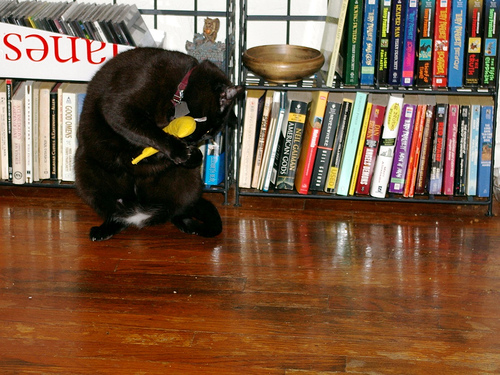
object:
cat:
[72, 44, 244, 243]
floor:
[0, 180, 499, 374]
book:
[335, 0, 360, 87]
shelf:
[238, 0, 495, 213]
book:
[360, 1, 377, 86]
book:
[376, 0, 391, 87]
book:
[389, 2, 403, 88]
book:
[400, 0, 418, 87]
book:
[416, 0, 433, 88]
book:
[433, 1, 450, 88]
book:
[448, 1, 465, 88]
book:
[462, 1, 484, 88]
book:
[480, 0, 496, 88]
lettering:
[3, 31, 121, 64]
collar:
[169, 62, 197, 111]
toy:
[129, 115, 198, 165]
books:
[455, 104, 472, 198]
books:
[2, 85, 12, 185]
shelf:
[1, 0, 237, 193]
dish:
[241, 42, 325, 85]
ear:
[222, 80, 247, 103]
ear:
[228, 106, 242, 128]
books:
[321, 1, 498, 89]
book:
[296, 89, 330, 193]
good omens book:
[60, 82, 85, 182]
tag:
[173, 96, 190, 119]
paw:
[168, 137, 190, 166]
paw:
[183, 145, 203, 169]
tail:
[186, 195, 224, 236]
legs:
[80, 207, 135, 244]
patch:
[110, 201, 155, 230]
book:
[477, 97, 494, 200]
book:
[204, 131, 224, 187]